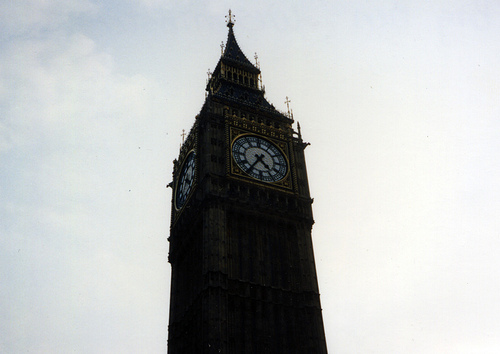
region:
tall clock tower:
[143, 57, 306, 349]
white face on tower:
[237, 136, 289, 176]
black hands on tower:
[242, 153, 289, 175]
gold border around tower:
[210, 107, 290, 189]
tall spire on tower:
[207, 0, 265, 92]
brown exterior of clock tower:
[181, 182, 320, 347]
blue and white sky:
[265, 2, 370, 154]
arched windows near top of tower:
[226, 67, 255, 89]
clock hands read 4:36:
[235, 145, 279, 175]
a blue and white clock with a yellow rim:
[231, 129, 292, 185]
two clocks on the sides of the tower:
[170, 129, 289, 209]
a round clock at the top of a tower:
[228, 129, 295, 189]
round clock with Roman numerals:
[229, 129, 291, 181]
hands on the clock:
[243, 152, 273, 177]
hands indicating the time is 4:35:
[243, 150, 273, 176]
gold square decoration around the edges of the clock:
[221, 110, 302, 200]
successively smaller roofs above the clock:
[173, 2, 305, 156]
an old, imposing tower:
[159, 4, 329, 351]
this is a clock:
[229, 130, 285, 190]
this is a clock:
[169, 155, 206, 203]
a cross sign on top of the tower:
[275, 85, 301, 127]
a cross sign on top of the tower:
[244, 31, 280, 82]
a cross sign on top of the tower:
[218, 0, 245, 35]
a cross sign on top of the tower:
[166, 110, 196, 156]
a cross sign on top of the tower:
[201, 28, 224, 61]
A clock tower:
[163, 8, 328, 349]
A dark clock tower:
[166, 6, 338, 352]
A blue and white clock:
[231, 130, 290, 186]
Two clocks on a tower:
[173, 136, 280, 209]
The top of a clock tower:
[206, 6, 264, 86]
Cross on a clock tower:
[283, 92, 292, 117]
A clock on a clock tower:
[173, 151, 208, 210]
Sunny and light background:
[3, 1, 499, 347]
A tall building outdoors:
[161, 2, 333, 350]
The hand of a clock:
[254, 153, 270, 170]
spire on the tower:
[206, 15, 251, 57]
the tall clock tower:
[169, 8, 321, 344]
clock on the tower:
[221, 131, 286, 180]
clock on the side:
[168, 155, 191, 203]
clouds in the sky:
[52, 87, 124, 175]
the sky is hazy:
[363, 95, 430, 237]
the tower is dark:
[179, 226, 292, 305]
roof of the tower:
[218, 48, 265, 90]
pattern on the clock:
[259, 149, 279, 161]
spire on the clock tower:
[176, 128, 184, 143]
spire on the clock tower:
[203, 65, 210, 80]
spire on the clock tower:
[250, 47, 260, 65]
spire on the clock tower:
[223, 6, 231, 22]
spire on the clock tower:
[205, 77, 215, 97]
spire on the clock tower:
[290, 117, 301, 137]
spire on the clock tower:
[251, 49, 258, 64]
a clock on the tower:
[227, 131, 297, 190]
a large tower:
[157, 7, 332, 352]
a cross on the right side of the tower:
[282, 92, 297, 121]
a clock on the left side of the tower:
[165, 146, 200, 217]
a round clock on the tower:
[225, 129, 295, 182]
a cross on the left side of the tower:
[176, 123, 190, 148]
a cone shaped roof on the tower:
[214, 7, 263, 77]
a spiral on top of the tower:
[218, 5, 240, 35]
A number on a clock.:
[277, 155, 284, 161]